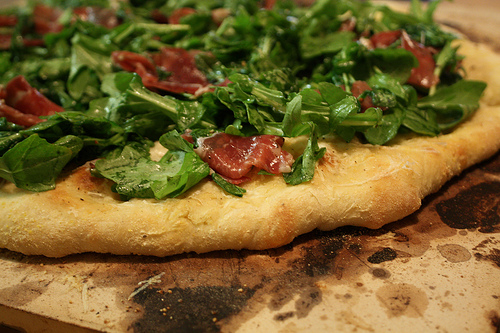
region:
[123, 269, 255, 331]
The grease stains on the paper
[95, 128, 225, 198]
The pizza has on lettuce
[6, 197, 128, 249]
The crust is yellow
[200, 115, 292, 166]
The pizza has on bacon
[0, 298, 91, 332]
The piece of table is brown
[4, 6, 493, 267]
The picture shows half a pizza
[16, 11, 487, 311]
this is a pizza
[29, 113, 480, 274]
crust on the pizza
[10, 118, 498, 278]
the crust is brown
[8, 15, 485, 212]
spinach on the pizza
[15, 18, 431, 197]
the spinach is green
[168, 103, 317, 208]
meat on the pizza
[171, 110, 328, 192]
meat is dark red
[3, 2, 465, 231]
multiple topping on pizza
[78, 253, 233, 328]
black spot on surface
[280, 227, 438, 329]
stain on the surface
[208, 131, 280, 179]
a piece of bacon on a pizza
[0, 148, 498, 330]
a greasy brown napkin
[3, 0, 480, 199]
spinach and bacon topping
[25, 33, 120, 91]
a spinach leaf on a pizza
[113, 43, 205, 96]
crumbled brown bacon pieces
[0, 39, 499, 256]
a toasted pizza crust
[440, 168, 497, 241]
a grease stain from a pizza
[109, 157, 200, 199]
a torn spinach leaf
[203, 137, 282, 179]
a wavy piece of bacon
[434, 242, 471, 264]
a round splatter of grease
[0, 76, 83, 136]
prosciutto on the hand made pizza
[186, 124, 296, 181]
prosciutto on the hand made pizza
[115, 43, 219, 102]
prosciutto on the hand made pizza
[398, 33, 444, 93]
prosciutto on the hand made pizza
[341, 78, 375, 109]
prosciutto on the hand made pizza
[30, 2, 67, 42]
prosciutto on the hand made pizza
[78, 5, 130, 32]
prosciutto on the hand made pizza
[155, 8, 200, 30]
prosciutto on the hand made pizza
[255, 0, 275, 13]
prosciutto on the hand made pizza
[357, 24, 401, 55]
prosciutto on the hand made pizza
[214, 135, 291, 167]
bacon on a pizza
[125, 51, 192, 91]
bacon on a piza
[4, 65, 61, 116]
bacon on a pizza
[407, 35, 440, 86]
bacon on a pizza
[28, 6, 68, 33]
bacon on a pizza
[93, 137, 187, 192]
basil on a pizza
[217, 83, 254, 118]
basil on a pizza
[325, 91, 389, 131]
basil on a pizza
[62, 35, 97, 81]
basil on a pizza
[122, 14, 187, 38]
basil on a pizza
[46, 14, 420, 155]
basil on spinach on top of a pizza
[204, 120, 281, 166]
Ham on top of the pizza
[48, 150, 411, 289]
flat bread on the board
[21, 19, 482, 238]
pizza with vegetable and meat